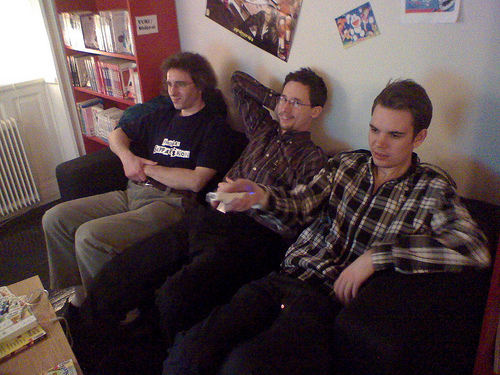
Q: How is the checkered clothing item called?
A: The clothing item is a shirt.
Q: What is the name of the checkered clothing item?
A: The clothing item is a shirt.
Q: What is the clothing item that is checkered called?
A: The clothing item is a shirt.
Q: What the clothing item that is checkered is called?
A: The clothing item is a shirt.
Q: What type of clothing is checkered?
A: The clothing is a shirt.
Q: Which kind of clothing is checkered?
A: The clothing is a shirt.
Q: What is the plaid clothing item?
A: The clothing item is a shirt.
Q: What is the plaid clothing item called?
A: The clothing item is a shirt.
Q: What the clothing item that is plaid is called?
A: The clothing item is a shirt.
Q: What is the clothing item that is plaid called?
A: The clothing item is a shirt.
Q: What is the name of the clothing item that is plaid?
A: The clothing item is a shirt.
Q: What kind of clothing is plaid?
A: The clothing is a shirt.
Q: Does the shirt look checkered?
A: Yes, the shirt is checkered.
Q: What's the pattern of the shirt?
A: The shirt is checkered.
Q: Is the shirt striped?
A: No, the shirt is checkered.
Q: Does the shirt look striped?
A: No, the shirt is checkered.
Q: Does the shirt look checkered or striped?
A: The shirt is checkered.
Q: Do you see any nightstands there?
A: No, there are no nightstands.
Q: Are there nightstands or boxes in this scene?
A: No, there are no nightstands or boxes.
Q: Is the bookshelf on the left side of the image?
A: Yes, the bookshelf is on the left of the image.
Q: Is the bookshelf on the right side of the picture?
A: No, the bookshelf is on the left of the image.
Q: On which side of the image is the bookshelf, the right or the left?
A: The bookshelf is on the left of the image.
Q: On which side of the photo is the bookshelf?
A: The bookshelf is on the left of the image.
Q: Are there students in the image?
A: No, there are no students.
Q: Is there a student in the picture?
A: No, there are no students.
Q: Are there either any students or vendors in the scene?
A: No, there are no students or vendors.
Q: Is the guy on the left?
A: Yes, the guy is on the left of the image.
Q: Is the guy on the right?
A: No, the guy is on the left of the image.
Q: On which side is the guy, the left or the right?
A: The guy is on the left of the image.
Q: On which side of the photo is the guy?
A: The guy is on the left of the image.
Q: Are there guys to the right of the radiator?
A: Yes, there is a guy to the right of the radiator.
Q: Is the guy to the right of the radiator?
A: Yes, the guy is to the right of the radiator.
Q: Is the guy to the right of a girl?
A: No, the guy is to the right of the radiator.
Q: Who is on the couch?
A: The men are on the couch.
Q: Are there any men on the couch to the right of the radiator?
A: Yes, there are men on the couch.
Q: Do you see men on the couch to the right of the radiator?
A: Yes, there are men on the couch.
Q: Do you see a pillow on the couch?
A: No, there are men on the couch.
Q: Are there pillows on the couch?
A: No, there are men on the couch.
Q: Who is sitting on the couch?
A: The men are sitting on the couch.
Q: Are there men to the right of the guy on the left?
A: Yes, there are men to the right of the guy.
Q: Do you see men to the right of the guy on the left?
A: Yes, there are men to the right of the guy.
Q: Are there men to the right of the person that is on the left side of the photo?
A: Yes, there are men to the right of the guy.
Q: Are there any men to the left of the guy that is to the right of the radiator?
A: No, the men are to the right of the guy.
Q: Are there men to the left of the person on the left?
A: No, the men are to the right of the guy.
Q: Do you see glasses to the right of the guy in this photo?
A: No, there are men to the right of the guy.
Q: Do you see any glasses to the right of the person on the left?
A: No, there are men to the right of the guy.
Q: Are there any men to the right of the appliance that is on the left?
A: Yes, there are men to the right of the radiator.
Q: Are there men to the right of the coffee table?
A: Yes, there are men to the right of the coffee table.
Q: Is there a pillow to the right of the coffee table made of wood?
A: No, there are men to the right of the coffee table.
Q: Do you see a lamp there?
A: No, there are no lamps.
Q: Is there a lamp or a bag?
A: No, there are no lamps or bags.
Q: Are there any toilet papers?
A: No, there are no toilet papers.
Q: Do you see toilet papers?
A: No, there are no toilet papers.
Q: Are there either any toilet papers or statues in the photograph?
A: No, there are no toilet papers or statues.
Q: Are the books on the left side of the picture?
A: Yes, the books are on the left of the image.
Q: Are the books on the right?
A: No, the books are on the left of the image.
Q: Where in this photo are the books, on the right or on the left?
A: The books are on the left of the image.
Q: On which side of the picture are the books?
A: The books are on the left of the image.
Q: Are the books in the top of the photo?
A: Yes, the books are in the top of the image.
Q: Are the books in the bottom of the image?
A: No, the books are in the top of the image.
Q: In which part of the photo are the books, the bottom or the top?
A: The books are in the top of the image.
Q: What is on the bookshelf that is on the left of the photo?
A: The books are on the bookshelf.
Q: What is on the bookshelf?
A: The books are on the bookshelf.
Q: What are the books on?
A: The books are on the bookshelf.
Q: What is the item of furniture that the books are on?
A: The piece of furniture is a bookshelf.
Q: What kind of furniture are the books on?
A: The books are on the bookshelf.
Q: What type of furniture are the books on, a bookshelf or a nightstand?
A: The books are on a bookshelf.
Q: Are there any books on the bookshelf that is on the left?
A: Yes, there are books on the bookshelf.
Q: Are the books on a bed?
A: No, the books are on the bookshelf.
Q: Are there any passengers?
A: No, there are no passengers.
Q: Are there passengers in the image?
A: No, there are no passengers.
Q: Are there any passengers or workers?
A: No, there are no passengers or workers.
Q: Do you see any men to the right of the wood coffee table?
A: Yes, there is a man to the right of the coffee table.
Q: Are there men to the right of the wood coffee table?
A: Yes, there is a man to the right of the coffee table.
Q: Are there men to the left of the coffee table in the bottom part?
A: No, the man is to the right of the coffee table.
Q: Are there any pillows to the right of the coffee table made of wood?
A: No, there is a man to the right of the coffee table.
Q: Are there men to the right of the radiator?
A: Yes, there is a man to the right of the radiator.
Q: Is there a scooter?
A: No, there are no scooters.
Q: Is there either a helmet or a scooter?
A: No, there are no scooters or helmets.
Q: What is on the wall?
A: The poster is on the wall.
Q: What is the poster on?
A: The poster is on the wall.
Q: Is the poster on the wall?
A: Yes, the poster is on the wall.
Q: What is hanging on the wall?
A: The poster is hanging on the wall.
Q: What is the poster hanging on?
A: The poster is hanging on the wall.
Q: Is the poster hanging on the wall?
A: Yes, the poster is hanging on the wall.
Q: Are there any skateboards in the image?
A: No, there are no skateboards.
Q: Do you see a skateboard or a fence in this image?
A: No, there are no skateboards or fences.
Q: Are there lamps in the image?
A: No, there are no lamps.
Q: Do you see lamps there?
A: No, there are no lamps.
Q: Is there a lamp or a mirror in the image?
A: No, there are no lamps or mirrors.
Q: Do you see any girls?
A: No, there are no girls.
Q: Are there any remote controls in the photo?
A: Yes, there is a remote control.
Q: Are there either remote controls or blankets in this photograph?
A: Yes, there is a remote control.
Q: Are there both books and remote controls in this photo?
A: Yes, there are both a remote control and a book.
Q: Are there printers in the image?
A: No, there are no printers.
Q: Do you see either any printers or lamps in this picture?
A: No, there are no printers or lamps.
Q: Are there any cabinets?
A: No, there are no cabinets.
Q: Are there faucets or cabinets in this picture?
A: No, there are no cabinets or faucets.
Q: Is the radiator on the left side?
A: Yes, the radiator is on the left of the image.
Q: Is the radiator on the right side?
A: No, the radiator is on the left of the image.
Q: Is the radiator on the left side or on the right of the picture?
A: The radiator is on the left of the image.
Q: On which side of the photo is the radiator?
A: The radiator is on the left of the image.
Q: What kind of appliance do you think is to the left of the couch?
A: The appliance is a radiator.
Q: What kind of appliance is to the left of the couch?
A: The appliance is a radiator.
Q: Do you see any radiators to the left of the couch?
A: Yes, there is a radiator to the left of the couch.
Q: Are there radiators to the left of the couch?
A: Yes, there is a radiator to the left of the couch.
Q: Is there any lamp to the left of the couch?
A: No, there is a radiator to the left of the couch.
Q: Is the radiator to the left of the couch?
A: Yes, the radiator is to the left of the couch.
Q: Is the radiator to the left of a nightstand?
A: No, the radiator is to the left of the couch.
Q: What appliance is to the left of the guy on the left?
A: The appliance is a radiator.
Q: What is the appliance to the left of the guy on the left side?
A: The appliance is a radiator.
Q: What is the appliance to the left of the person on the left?
A: The appliance is a radiator.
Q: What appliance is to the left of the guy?
A: The appliance is a radiator.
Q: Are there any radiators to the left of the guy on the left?
A: Yes, there is a radiator to the left of the guy.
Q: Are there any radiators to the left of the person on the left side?
A: Yes, there is a radiator to the left of the guy.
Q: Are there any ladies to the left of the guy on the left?
A: No, there is a radiator to the left of the guy.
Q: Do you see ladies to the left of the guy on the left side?
A: No, there is a radiator to the left of the guy.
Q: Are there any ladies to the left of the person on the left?
A: No, there is a radiator to the left of the guy.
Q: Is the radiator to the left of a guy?
A: Yes, the radiator is to the left of a guy.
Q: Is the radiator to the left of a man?
A: Yes, the radiator is to the left of a man.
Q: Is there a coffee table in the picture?
A: Yes, there is a coffee table.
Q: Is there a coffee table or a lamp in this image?
A: Yes, there is a coffee table.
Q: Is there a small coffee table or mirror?
A: Yes, there is a small coffee table.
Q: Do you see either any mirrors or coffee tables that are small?
A: Yes, the coffee table is small.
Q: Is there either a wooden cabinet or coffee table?
A: Yes, there is a wood coffee table.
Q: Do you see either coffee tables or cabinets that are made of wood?
A: Yes, the coffee table is made of wood.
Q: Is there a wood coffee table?
A: Yes, there is a wood coffee table.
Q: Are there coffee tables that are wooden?
A: Yes, there is a coffee table that is wooden.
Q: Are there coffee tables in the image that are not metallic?
A: Yes, there is a wooden coffee table.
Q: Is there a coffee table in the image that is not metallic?
A: Yes, there is a wooden coffee table.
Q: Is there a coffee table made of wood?
A: Yes, there is a coffee table that is made of wood.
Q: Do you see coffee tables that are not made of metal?
A: Yes, there is a coffee table that is made of wood.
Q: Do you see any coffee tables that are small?
A: Yes, there is a small coffee table.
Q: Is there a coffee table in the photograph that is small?
A: Yes, there is a coffee table that is small.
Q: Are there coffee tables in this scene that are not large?
A: Yes, there is a small coffee table.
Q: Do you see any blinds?
A: No, there are no blinds.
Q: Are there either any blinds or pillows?
A: No, there are no blinds or pillows.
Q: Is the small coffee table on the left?
A: Yes, the coffee table is on the left of the image.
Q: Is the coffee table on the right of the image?
A: No, the coffee table is on the left of the image.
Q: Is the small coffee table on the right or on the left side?
A: The coffee table is on the left of the image.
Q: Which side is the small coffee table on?
A: The coffee table is on the left of the image.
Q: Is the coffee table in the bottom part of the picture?
A: Yes, the coffee table is in the bottom of the image.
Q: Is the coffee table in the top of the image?
A: No, the coffee table is in the bottom of the image.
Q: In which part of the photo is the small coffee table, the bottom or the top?
A: The coffee table is in the bottom of the image.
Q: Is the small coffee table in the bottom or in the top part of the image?
A: The coffee table is in the bottom of the image.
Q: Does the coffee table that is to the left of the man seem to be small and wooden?
A: Yes, the coffee table is small and wooden.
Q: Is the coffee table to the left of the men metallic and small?
A: No, the coffee table is small but wooden.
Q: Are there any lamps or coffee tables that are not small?
A: No, there is a coffee table but it is small.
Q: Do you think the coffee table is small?
A: Yes, the coffee table is small.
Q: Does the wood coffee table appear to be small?
A: Yes, the coffee table is small.